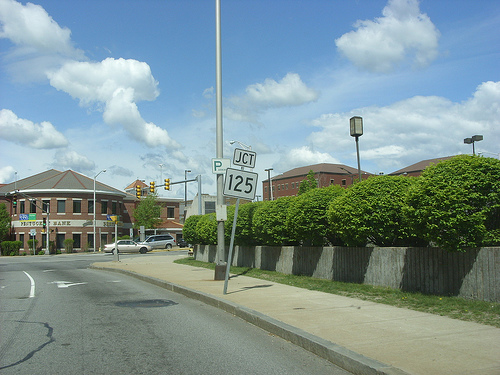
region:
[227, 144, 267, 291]
street sign on sidewalk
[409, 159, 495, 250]
green privacy bush on side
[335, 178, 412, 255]
green privacy bush on side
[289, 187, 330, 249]
green privacy bush on side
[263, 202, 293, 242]
green privacy bush on side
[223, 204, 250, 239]
green privacy bush on side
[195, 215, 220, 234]
green privacy bush on side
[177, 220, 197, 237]
green privacy bush on side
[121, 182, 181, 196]
yellow traffic lights overhead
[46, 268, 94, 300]
white arrows on street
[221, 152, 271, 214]
a small display on road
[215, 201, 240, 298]
a small pillar holding number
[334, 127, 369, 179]
a small height light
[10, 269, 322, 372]
a very clean road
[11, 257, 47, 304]
a small white line on road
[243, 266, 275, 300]
shadow of the poll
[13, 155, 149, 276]
a big neat building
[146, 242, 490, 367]
a foot path across the road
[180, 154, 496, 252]
a group of green trees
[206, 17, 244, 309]
a very long electric poll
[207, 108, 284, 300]
street pole by side of rode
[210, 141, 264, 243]
numbers on top of sign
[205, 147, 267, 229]
street signs on pole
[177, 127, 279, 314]
tilted street pole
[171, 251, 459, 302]
wooden wall next to road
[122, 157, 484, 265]
green bushes by wooden fence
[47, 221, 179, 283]
cars driving in background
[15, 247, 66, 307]
white paint line on street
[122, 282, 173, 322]
pot hole in street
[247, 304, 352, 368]
large curb by sidewalk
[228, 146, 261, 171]
JCT on a black and white sign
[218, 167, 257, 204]
125 on a black and white sign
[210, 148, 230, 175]
a green letter P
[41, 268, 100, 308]
a forward and right turn arrow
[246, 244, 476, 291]
multiple shadows from bushes on a fence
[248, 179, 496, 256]
a line of uniform trimmed bushes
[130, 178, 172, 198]
a group of three traffic lights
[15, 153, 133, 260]
a round shaped building front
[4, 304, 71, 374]
a black crack in the asphalt that has been filled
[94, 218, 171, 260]
two vehicles passing each other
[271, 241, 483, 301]
low gray cement wall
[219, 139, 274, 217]
street sign for JCT 125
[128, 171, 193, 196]
three yellow stoplights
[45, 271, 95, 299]
white arrows on the street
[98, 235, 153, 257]
gold sedan on road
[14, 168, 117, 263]
building with brick exterior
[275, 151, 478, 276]
green rounded hedges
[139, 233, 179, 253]
silver minivan on road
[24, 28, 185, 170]
daytime sky with fluffy white clouds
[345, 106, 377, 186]
tall black light